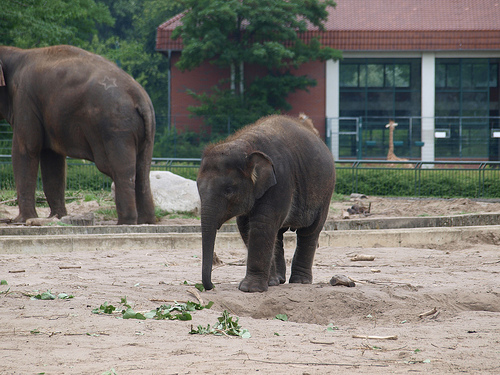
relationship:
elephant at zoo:
[196, 113, 336, 293] [2, 152, 497, 373]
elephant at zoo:
[2, 45, 161, 224] [2, 152, 497, 373]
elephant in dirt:
[196, 113, 336, 293] [2, 152, 497, 373]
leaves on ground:
[2, 280, 251, 340] [2, 240, 495, 371]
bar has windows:
[155, 0, 499, 168] [338, 53, 500, 163]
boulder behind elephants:
[111, 169, 201, 217] [1, 46, 336, 293]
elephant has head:
[196, 113, 336, 293] [197, 142, 254, 292]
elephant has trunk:
[196, 113, 336, 293] [200, 197, 217, 292]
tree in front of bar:
[173, 3, 344, 160] [155, 0, 499, 168]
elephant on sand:
[196, 113, 336, 293] [2, 152, 497, 373]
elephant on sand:
[2, 45, 161, 224] [2, 152, 497, 373]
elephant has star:
[2, 45, 161, 224] [100, 76, 118, 90]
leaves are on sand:
[2, 280, 251, 340] [2, 152, 497, 373]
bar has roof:
[155, 0, 499, 168] [154, 3, 499, 51]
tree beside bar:
[173, 3, 344, 160] [155, 0, 499, 168]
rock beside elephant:
[332, 275, 356, 285] [196, 113, 336, 293]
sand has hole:
[2, 152, 497, 373] [210, 286, 402, 329]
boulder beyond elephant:
[111, 169, 201, 217] [2, 45, 161, 224]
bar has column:
[155, 0, 499, 168] [326, 56, 340, 164]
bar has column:
[155, 0, 499, 168] [423, 55, 436, 169]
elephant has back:
[2, 45, 161, 224] [23, 47, 155, 169]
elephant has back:
[196, 113, 336, 293] [234, 115, 335, 199]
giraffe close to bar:
[385, 121, 414, 168] [155, 0, 499, 168]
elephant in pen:
[2, 45, 161, 224] [2, 152, 497, 373]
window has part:
[487, 59, 497, 90] [489, 61, 498, 86]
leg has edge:
[139, 164, 156, 224] [147, 181, 157, 223]